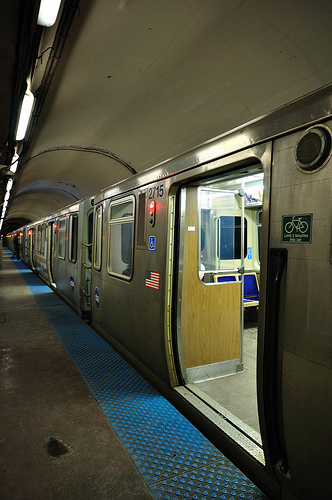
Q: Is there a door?
A: Yes, there is a door.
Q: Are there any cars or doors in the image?
A: Yes, there is a door.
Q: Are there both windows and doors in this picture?
A: Yes, there are both a door and a window.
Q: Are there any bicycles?
A: Yes, there is a bicycle.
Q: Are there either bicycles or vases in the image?
A: Yes, there is a bicycle.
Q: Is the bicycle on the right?
A: Yes, the bicycle is on the right of the image.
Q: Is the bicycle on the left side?
A: No, the bicycle is on the right of the image.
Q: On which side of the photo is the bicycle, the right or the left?
A: The bicycle is on the right of the image.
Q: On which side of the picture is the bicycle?
A: The bicycle is on the right of the image.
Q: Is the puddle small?
A: Yes, the puddle is small.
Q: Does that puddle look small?
A: Yes, the puddle is small.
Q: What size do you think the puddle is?
A: The puddle is small.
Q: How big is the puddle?
A: The puddle is small.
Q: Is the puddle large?
A: No, the puddle is small.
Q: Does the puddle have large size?
A: No, the puddle is small.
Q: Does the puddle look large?
A: No, the puddle is small.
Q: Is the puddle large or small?
A: The puddle is small.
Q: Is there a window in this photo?
A: Yes, there is a window.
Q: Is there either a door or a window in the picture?
A: Yes, there is a window.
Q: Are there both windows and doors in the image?
A: Yes, there are both a window and a door.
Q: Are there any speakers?
A: Yes, there is a speaker.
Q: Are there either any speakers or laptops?
A: Yes, there is a speaker.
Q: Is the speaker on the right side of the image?
A: Yes, the speaker is on the right of the image.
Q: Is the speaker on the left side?
A: No, the speaker is on the right of the image.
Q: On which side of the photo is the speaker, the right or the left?
A: The speaker is on the right of the image.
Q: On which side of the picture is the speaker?
A: The speaker is on the right of the image.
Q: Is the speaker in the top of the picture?
A: Yes, the speaker is in the top of the image.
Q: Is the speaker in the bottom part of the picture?
A: No, the speaker is in the top of the image.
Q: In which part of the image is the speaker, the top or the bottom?
A: The speaker is in the top of the image.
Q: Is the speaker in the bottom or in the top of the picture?
A: The speaker is in the top of the image.